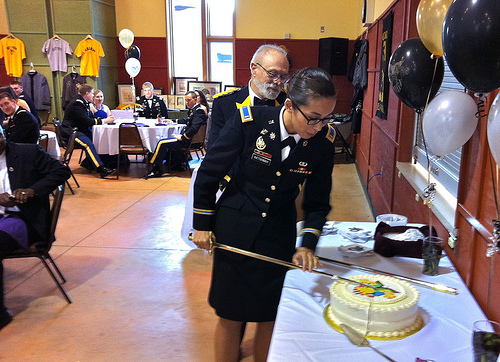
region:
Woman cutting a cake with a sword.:
[186, 65, 424, 360]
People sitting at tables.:
[2, 70, 207, 316]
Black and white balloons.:
[381, 66, 496, 156]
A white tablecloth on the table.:
[265, 215, 495, 360]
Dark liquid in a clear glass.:
[468, 317, 495, 358]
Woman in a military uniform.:
[195, 108, 332, 319]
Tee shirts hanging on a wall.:
[0, 51, 105, 76]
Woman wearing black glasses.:
[290, 100, 335, 121]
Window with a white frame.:
[395, 0, 470, 235]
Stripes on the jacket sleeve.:
[190, 202, 215, 223]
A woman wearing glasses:
[267, 70, 350, 144]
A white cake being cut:
[307, 270, 429, 341]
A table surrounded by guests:
[57, 67, 215, 175]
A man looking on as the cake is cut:
[243, 40, 298, 104]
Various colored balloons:
[380, 0, 498, 157]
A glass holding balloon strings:
[416, 228, 448, 275]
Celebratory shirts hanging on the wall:
[2, 29, 112, 80]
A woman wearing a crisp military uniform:
[177, 70, 349, 359]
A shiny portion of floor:
[66, 196, 184, 360]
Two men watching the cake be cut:
[0, 83, 37, 142]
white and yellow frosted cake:
[323, 271, 428, 343]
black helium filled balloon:
[385, 37, 441, 117]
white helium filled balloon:
[419, 86, 484, 168]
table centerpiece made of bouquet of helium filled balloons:
[115, 23, 144, 120]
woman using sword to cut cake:
[184, 66, 429, 343]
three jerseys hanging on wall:
[2, 28, 105, 80]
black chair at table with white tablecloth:
[111, 120, 153, 177]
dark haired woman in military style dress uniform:
[188, 63, 341, 360]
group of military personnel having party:
[2, 32, 489, 359]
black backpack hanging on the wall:
[348, 35, 373, 94]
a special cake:
[326, 261, 428, 344]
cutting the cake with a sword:
[188, 213, 423, 329]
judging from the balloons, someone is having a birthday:
[107, 23, 155, 91]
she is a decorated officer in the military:
[224, 115, 323, 194]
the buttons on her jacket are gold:
[260, 163, 285, 225]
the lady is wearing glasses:
[281, 94, 338, 133]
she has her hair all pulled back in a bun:
[272, 61, 352, 136]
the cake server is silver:
[332, 313, 398, 360]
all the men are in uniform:
[55, 81, 225, 171]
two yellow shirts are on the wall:
[0, 35, 112, 81]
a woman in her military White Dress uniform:
[196, 68, 338, 360]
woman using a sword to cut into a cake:
[192, 61, 437, 341]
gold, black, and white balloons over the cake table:
[386, 0, 498, 180]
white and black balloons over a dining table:
[123, 24, 147, 125]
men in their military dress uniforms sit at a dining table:
[52, 74, 215, 185]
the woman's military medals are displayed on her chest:
[283, 149, 318, 179]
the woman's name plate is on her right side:
[248, 153, 272, 165]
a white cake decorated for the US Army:
[331, 269, 419, 334]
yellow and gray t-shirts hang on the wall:
[0, 35, 108, 85]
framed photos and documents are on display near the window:
[107, 71, 245, 117]